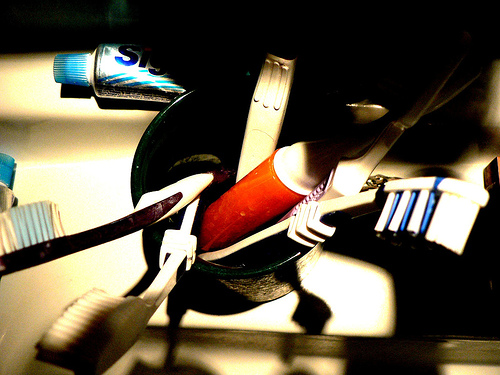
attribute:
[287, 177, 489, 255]
toothbrush — white, blue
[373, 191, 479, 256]
bristles — blue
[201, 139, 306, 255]
handle — orange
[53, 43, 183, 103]
toothpaste — blue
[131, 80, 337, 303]
holder — toothbrush holder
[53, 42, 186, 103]
tube — toothpaste tube, blue, white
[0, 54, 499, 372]
counter — white